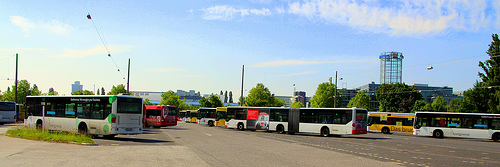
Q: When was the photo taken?
A: Daytime.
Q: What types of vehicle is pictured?
A: Buses.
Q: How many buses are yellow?
A: Three.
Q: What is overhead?
A: Power lines.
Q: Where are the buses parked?
A: Parking lot.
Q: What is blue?
A: Sky.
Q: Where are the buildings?
A: Background.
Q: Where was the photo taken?
A: Near buses.